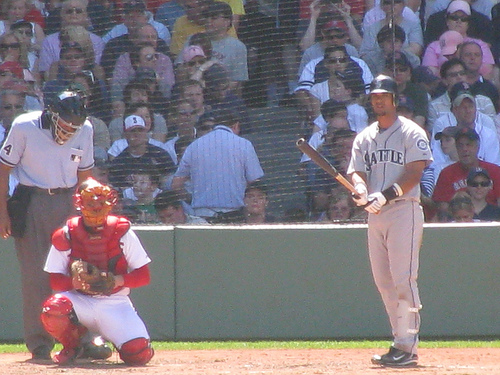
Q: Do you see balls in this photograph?
A: No, there are no balls.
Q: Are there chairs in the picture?
A: No, there are no chairs.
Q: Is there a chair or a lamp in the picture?
A: No, there are no chairs or lamps.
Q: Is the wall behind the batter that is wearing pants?
A: Yes, the wall is behind the batter.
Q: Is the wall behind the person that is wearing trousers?
A: Yes, the wall is behind the batter.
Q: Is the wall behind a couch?
A: No, the wall is behind the batter.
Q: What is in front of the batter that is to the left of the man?
A: The glove is in front of the batter.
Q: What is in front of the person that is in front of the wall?
A: The glove is in front of the batter.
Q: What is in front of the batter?
A: The glove is in front of the batter.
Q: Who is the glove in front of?
A: The glove is in front of the batter.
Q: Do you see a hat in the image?
A: Yes, there is a hat.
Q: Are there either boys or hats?
A: Yes, there is a hat.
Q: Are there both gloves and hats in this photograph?
A: Yes, there are both a hat and gloves.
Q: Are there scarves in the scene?
A: No, there are no scarves.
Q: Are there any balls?
A: No, there are no balls.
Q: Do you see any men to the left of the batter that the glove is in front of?
A: Yes, there is a man to the left of the batter.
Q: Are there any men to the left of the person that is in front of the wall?
A: Yes, there is a man to the left of the batter.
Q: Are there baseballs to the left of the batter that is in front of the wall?
A: No, there is a man to the left of the batter.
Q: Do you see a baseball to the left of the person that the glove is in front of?
A: No, there is a man to the left of the batter.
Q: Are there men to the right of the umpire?
A: Yes, there is a man to the right of the umpire.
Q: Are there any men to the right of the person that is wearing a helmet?
A: Yes, there is a man to the right of the umpire.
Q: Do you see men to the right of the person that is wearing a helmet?
A: Yes, there is a man to the right of the umpire.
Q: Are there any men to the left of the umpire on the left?
A: No, the man is to the right of the umpire.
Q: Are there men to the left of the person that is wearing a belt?
A: No, the man is to the right of the umpire.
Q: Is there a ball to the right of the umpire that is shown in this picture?
A: No, there is a man to the right of the umpire.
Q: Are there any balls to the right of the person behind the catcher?
A: No, there is a man to the right of the umpire.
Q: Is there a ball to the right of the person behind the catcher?
A: No, there is a man to the right of the umpire.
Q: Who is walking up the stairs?
A: The man is walking up the stairs.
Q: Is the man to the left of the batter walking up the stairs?
A: Yes, the man is walking up the stairs.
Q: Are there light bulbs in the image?
A: No, there are no light bulbs.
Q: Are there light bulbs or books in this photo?
A: No, there are no light bulbs or books.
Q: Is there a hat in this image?
A: Yes, there is a hat.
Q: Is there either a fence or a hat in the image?
A: Yes, there is a hat.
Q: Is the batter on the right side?
A: Yes, the batter is on the right of the image.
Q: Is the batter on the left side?
A: No, the batter is on the right of the image.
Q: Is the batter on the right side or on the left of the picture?
A: The batter is on the right of the image.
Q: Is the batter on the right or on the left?
A: The batter is on the right of the image.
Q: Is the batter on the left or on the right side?
A: The batter is on the right of the image.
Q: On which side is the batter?
A: The batter is on the right of the image.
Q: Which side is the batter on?
A: The batter is on the right of the image.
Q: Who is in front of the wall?
A: The batter is in front of the wall.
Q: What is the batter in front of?
A: The batter is in front of the wall.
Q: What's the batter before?
A: The batter is in front of the wall.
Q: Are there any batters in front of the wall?
A: Yes, there is a batter in front of the wall.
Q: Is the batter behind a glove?
A: Yes, the batter is behind a glove.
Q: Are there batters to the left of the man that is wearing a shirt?
A: Yes, there is a batter to the left of the man.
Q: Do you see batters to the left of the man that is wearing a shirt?
A: Yes, there is a batter to the left of the man.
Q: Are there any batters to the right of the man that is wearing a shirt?
A: No, the batter is to the left of the man.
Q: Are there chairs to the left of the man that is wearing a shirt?
A: No, there is a batter to the left of the man.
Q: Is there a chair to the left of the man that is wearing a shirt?
A: No, there is a batter to the left of the man.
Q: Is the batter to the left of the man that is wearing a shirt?
A: Yes, the batter is to the left of the man.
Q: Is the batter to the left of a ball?
A: No, the batter is to the left of the man.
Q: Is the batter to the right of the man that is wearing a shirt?
A: No, the batter is to the left of the man.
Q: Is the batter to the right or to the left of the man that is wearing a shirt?
A: The batter is to the left of the man.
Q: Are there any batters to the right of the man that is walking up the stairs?
A: Yes, there is a batter to the right of the man.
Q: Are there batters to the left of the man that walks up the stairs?
A: No, the batter is to the right of the man.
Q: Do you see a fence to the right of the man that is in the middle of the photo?
A: No, there is a batter to the right of the man.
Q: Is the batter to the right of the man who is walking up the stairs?
A: Yes, the batter is to the right of the man.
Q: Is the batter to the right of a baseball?
A: No, the batter is to the right of the man.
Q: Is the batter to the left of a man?
A: No, the batter is to the right of a man.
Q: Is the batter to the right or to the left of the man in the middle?
A: The batter is to the right of the man.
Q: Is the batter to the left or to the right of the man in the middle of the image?
A: The batter is to the right of the man.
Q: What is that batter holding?
A: The batter is holding the bat.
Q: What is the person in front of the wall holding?
A: The batter is holding the bat.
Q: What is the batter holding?
A: The batter is holding the bat.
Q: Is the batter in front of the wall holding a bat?
A: Yes, the batter is holding a bat.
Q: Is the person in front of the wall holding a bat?
A: Yes, the batter is holding a bat.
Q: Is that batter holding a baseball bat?
A: No, the batter is holding a bat.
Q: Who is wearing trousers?
A: The batter is wearing trousers.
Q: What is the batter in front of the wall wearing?
A: The batter is wearing trousers.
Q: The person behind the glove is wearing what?
A: The batter is wearing trousers.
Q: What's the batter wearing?
A: The batter is wearing trousers.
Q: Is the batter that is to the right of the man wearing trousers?
A: Yes, the batter is wearing trousers.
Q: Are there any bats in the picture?
A: Yes, there is a bat.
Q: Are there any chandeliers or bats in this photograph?
A: Yes, there is a bat.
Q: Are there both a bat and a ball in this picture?
A: No, there is a bat but no balls.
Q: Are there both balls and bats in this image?
A: No, there is a bat but no balls.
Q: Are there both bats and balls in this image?
A: No, there is a bat but no balls.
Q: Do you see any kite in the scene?
A: No, there are no kites.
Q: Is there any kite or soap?
A: No, there are no kites or soaps.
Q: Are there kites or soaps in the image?
A: No, there are no kites or soaps.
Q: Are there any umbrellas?
A: No, there are no umbrellas.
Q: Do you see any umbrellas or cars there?
A: No, there are no umbrellas or cars.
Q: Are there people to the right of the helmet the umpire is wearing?
A: Yes, there are people to the right of the helmet.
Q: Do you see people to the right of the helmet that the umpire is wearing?
A: Yes, there are people to the right of the helmet.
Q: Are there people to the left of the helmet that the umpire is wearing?
A: No, the people are to the right of the helmet.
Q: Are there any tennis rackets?
A: No, there are no tennis rackets.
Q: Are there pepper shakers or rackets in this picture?
A: No, there are no rackets or pepper shakers.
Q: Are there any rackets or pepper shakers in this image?
A: No, there are no rackets or pepper shakers.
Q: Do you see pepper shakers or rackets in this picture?
A: No, there are no rackets or pepper shakers.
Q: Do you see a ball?
A: No, there are no balls.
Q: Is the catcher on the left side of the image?
A: Yes, the catcher is on the left of the image.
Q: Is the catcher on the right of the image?
A: No, the catcher is on the left of the image.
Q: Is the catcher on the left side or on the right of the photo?
A: The catcher is on the left of the image.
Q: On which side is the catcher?
A: The catcher is on the left of the image.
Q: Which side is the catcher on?
A: The catcher is on the left of the image.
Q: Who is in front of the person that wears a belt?
A: The catcher is in front of the umpire.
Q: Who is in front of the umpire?
A: The catcher is in front of the umpire.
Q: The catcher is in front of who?
A: The catcher is in front of the umpire.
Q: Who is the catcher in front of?
A: The catcher is in front of the umpire.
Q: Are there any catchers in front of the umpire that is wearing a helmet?
A: Yes, there is a catcher in front of the umpire.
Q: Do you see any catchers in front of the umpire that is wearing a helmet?
A: Yes, there is a catcher in front of the umpire.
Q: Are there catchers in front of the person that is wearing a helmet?
A: Yes, there is a catcher in front of the umpire.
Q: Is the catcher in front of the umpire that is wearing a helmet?
A: Yes, the catcher is in front of the umpire.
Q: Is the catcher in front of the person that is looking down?
A: Yes, the catcher is in front of the umpire.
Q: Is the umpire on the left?
A: Yes, the umpire is on the left of the image.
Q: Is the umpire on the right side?
A: No, the umpire is on the left of the image.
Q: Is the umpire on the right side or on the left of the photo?
A: The umpire is on the left of the image.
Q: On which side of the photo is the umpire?
A: The umpire is on the left of the image.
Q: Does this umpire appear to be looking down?
A: Yes, the umpire is looking down.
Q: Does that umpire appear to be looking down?
A: Yes, the umpire is looking down.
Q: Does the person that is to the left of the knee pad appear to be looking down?
A: Yes, the umpire is looking down.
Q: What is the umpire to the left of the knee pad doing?
A: The umpire is looking down.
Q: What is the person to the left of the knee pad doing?
A: The umpire is looking down.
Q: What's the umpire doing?
A: The umpire is looking down.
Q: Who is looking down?
A: The umpire is looking down.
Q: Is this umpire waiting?
A: No, the umpire is looking down.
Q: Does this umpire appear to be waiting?
A: No, the umpire is looking down.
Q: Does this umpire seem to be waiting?
A: No, the umpire is looking down.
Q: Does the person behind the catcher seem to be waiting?
A: No, the umpire is looking down.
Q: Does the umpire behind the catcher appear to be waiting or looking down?
A: The umpire is looking down.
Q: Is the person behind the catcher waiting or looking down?
A: The umpire is looking down.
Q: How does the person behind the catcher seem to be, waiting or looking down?
A: The umpire is looking down.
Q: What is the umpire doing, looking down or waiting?
A: The umpire is looking down.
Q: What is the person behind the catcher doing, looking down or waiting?
A: The umpire is looking down.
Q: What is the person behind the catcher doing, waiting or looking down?
A: The umpire is looking down.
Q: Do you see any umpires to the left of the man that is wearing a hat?
A: Yes, there is an umpire to the left of the man.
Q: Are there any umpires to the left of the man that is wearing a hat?
A: Yes, there is an umpire to the left of the man.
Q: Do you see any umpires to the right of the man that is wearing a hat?
A: No, the umpire is to the left of the man.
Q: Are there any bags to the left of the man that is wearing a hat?
A: No, there is an umpire to the left of the man.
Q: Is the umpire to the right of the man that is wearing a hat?
A: No, the umpire is to the left of the man.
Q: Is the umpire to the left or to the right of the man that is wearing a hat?
A: The umpire is to the left of the man.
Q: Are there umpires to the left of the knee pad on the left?
A: Yes, there is an umpire to the left of the knee pad.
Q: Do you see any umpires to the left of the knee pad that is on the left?
A: Yes, there is an umpire to the left of the knee pad.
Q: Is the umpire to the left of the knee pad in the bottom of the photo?
A: Yes, the umpire is to the left of the knee pad.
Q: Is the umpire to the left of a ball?
A: No, the umpire is to the left of the knee pad.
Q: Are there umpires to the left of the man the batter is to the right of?
A: Yes, there is an umpire to the left of the man.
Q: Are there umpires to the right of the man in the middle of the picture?
A: No, the umpire is to the left of the man.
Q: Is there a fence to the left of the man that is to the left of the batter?
A: No, there is an umpire to the left of the man.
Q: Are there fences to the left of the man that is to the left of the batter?
A: No, there is an umpire to the left of the man.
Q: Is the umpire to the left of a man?
A: Yes, the umpire is to the left of a man.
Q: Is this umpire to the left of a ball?
A: No, the umpire is to the left of a man.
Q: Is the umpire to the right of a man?
A: No, the umpire is to the left of a man.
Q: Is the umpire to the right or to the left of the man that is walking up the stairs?
A: The umpire is to the left of the man.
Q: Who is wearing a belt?
A: The umpire is wearing a belt.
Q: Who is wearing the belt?
A: The umpire is wearing a belt.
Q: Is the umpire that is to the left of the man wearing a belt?
A: Yes, the umpire is wearing a belt.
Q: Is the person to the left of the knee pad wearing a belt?
A: Yes, the umpire is wearing a belt.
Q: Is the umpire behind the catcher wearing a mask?
A: No, the umpire is wearing a belt.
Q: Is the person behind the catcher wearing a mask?
A: No, the umpire is wearing a belt.